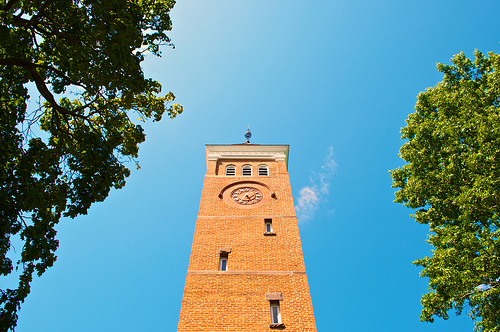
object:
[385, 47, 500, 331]
tree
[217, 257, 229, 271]
window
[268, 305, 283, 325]
window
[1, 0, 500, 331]
sky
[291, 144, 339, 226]
cloud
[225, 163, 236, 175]
window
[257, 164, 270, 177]
window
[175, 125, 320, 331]
building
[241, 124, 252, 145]
object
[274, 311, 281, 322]
part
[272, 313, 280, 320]
part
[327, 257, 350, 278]
part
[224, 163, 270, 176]
row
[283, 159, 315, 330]
edge